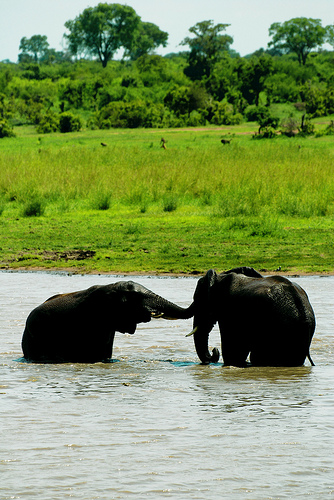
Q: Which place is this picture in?
A: It is at the river.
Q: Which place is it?
A: It is a river.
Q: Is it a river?
A: Yes, it is a river.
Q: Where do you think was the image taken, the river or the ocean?
A: It was taken at the river.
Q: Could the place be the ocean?
A: No, it is the river.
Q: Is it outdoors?
A: Yes, it is outdoors.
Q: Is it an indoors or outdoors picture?
A: It is outdoors.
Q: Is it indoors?
A: No, it is outdoors.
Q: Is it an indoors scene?
A: No, it is outdoors.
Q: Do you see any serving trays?
A: No, there are no serving trays.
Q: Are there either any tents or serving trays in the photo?
A: No, there are no serving trays or tents.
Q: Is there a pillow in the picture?
A: No, there are no pillows.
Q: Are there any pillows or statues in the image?
A: No, there are no pillows or statues.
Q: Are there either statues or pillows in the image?
A: No, there are no pillows or statues.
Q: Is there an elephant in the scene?
A: Yes, there is an elephant.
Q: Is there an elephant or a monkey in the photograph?
A: Yes, there is an elephant.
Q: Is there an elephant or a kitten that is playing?
A: Yes, the elephant is playing.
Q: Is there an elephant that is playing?
A: Yes, there is an elephant that is playing.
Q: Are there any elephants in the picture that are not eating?
A: Yes, there is an elephant that is playing.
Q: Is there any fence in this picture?
A: No, there are no fences.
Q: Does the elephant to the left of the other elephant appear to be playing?
A: Yes, the elephant is playing.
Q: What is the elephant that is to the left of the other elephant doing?
A: The elephant is playing.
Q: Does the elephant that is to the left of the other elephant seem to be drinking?
A: No, the elephant is playing.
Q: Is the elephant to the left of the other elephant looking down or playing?
A: The elephant is playing.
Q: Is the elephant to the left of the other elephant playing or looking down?
A: The elephant is playing.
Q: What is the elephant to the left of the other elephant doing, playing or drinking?
A: The elephant is playing.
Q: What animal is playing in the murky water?
A: The elephant is playing in the water.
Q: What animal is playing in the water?
A: The elephant is playing in the water.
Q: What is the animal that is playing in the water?
A: The animal is an elephant.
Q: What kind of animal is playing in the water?
A: The animal is an elephant.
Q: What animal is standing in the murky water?
A: The elephant is standing in the water.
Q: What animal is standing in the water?
A: The elephant is standing in the water.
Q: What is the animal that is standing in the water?
A: The animal is an elephant.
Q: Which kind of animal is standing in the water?
A: The animal is an elephant.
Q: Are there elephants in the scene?
A: Yes, there is an elephant.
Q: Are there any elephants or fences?
A: Yes, there is an elephant.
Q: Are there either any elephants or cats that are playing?
A: Yes, the elephant is playing.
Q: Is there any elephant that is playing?
A: Yes, there is an elephant that is playing.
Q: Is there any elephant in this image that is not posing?
A: Yes, there is an elephant that is playing.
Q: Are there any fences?
A: No, there are no fences.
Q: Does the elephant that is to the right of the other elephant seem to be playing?
A: Yes, the elephant is playing.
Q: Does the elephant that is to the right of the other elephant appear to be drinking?
A: No, the elephant is playing.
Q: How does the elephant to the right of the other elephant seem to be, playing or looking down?
A: The elephant is playing.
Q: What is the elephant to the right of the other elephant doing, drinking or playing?
A: The elephant is playing.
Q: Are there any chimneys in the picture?
A: No, there are no chimneys.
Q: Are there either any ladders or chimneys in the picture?
A: No, there are no chimneys or ladders.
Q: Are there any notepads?
A: No, there are no notepads.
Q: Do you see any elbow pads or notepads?
A: No, there are no notepads or elbow pads.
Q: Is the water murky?
A: Yes, the water is murky.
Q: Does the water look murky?
A: Yes, the water is murky.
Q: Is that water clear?
A: No, the water is murky.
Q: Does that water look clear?
A: No, the water is murky.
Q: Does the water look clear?
A: No, the water is murky.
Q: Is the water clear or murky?
A: The water is murky.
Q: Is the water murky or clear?
A: The water is murky.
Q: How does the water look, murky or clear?
A: The water is murky.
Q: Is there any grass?
A: Yes, there is grass.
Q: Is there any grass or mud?
A: Yes, there is grass.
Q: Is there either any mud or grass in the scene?
A: Yes, there is grass.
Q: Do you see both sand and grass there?
A: No, there is grass but no sand.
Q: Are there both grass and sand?
A: No, there is grass but no sand.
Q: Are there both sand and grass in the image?
A: No, there is grass but no sand.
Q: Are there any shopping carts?
A: No, there are no shopping carts.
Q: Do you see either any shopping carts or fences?
A: No, there are no shopping carts or fences.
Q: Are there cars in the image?
A: No, there are no cars.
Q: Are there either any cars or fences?
A: No, there are no cars or fences.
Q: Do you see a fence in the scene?
A: No, there are no fences.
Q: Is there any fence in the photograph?
A: No, there are no fences.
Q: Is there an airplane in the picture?
A: No, there are no airplanes.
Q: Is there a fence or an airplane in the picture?
A: No, there are no airplanes or fences.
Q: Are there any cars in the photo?
A: No, there are no cars.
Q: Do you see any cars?
A: No, there are no cars.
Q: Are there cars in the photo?
A: No, there are no cars.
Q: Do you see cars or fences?
A: No, there are no cars or fences.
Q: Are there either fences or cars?
A: No, there are no cars or fences.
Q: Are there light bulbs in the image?
A: No, there are no light bulbs.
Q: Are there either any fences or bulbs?
A: No, there are no bulbs or fences.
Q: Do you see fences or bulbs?
A: No, there are no bulbs or fences.